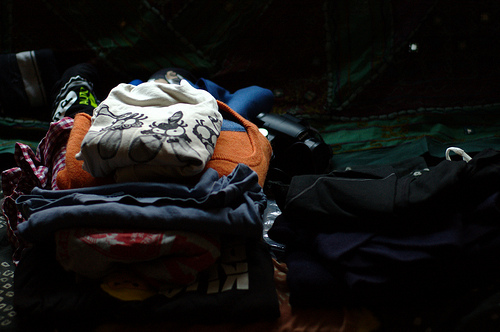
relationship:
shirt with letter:
[17, 242, 282, 329] [222, 263, 249, 291]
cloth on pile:
[201, 80, 267, 112] [169, 66, 301, 161]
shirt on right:
[281, 160, 493, 317] [345, 33, 483, 319]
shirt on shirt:
[84, 75, 214, 172] [76, 227, 178, 247]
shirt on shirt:
[84, 75, 214, 172] [13, 126, 70, 191]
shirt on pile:
[84, 75, 214, 172] [20, 79, 273, 316]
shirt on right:
[265, 150, 499, 319] [336, 54, 478, 271]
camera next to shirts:
[252, 109, 342, 174] [9, 71, 268, 331]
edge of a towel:
[71, 217, 171, 229] [46, 157, 250, 238]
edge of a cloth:
[64, 217, 174, 231] [82, 75, 227, 181]